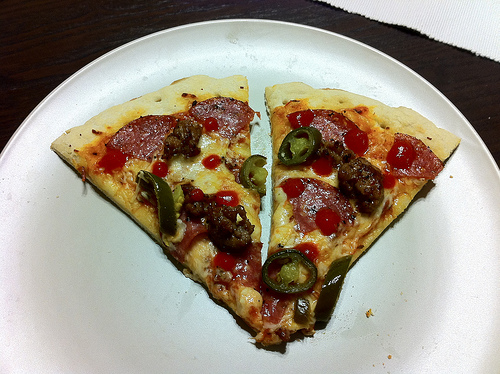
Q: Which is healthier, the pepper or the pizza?
A: The pepper is healthier than the pizza.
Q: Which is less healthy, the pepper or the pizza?
A: The pizza is less healthy than the pepper.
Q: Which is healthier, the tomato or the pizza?
A: The tomato is healthier than the pizza.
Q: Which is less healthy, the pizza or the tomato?
A: The pizza is less healthy than the tomato.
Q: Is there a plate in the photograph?
A: Yes, there is a plate.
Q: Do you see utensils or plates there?
A: Yes, there is a plate.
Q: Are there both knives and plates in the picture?
A: No, there is a plate but no knives.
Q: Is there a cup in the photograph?
A: No, there are no cups.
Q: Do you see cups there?
A: No, there are no cups.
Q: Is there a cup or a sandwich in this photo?
A: No, there are no cups or sandwiches.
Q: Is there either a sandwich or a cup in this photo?
A: No, there are no cups or sandwiches.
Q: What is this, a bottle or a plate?
A: This is a plate.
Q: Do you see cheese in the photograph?
A: Yes, there is cheese.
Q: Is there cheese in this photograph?
A: Yes, there is cheese.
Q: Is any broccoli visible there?
A: No, there is no broccoli.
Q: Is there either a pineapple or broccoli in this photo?
A: No, there are no broccoli or pineapples.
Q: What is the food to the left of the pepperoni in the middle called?
A: The food is cheese.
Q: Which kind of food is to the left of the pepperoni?
A: The food is cheese.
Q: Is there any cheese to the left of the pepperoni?
A: Yes, there is cheese to the left of the pepperoni.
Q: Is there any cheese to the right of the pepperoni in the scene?
A: No, the cheese is to the left of the pepperoni.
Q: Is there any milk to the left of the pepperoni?
A: No, there is cheese to the left of the pepperoni.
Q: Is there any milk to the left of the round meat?
A: No, there is cheese to the left of the pepperoni.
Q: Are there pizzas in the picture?
A: Yes, there is a pizza.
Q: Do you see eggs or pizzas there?
A: Yes, there is a pizza.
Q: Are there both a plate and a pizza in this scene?
A: Yes, there are both a pizza and a plate.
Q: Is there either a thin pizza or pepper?
A: Yes, there is a thin pizza.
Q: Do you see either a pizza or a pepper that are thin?
A: Yes, the pizza is thin.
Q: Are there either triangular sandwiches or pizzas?
A: Yes, there is a triangular pizza.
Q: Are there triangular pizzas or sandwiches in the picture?
A: Yes, there is a triangular pizza.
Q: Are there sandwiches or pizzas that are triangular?
A: Yes, the pizza is triangular.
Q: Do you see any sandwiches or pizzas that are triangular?
A: Yes, the pizza is triangular.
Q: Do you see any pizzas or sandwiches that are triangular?
A: Yes, the pizza is triangular.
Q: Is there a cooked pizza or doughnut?
A: Yes, there is a cooked pizza.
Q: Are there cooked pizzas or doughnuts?
A: Yes, there is a cooked pizza.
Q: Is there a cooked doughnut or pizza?
A: Yes, there is a cooked pizza.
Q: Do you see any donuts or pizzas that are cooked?
A: Yes, the pizza is cooked.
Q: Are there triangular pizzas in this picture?
A: Yes, there is a triangular pizza.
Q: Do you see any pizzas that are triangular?
A: Yes, there is a pizza that is triangular.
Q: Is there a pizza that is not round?
A: Yes, there is a triangular pizza.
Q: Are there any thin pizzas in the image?
A: Yes, there is a thin pizza.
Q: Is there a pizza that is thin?
A: Yes, there is a pizza that is thin.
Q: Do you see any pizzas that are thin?
A: Yes, there is a pizza that is thin.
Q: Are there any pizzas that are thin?
A: Yes, there is a pizza that is thin.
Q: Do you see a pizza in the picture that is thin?
A: Yes, there is a pizza that is thin.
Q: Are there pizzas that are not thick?
A: Yes, there is a thin pizza.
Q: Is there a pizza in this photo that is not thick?
A: Yes, there is a thin pizza.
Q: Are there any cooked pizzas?
A: Yes, there is a cooked pizza.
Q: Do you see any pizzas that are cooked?
A: Yes, there is a pizza that is cooked.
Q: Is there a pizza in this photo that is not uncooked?
A: Yes, there is an cooked pizza.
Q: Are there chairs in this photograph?
A: No, there are no chairs.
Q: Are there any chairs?
A: No, there are no chairs.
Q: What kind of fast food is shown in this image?
A: The fast food is a pizza.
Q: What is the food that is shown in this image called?
A: The food is a pizza.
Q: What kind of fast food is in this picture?
A: The fast food is a pizza.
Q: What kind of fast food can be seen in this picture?
A: The fast food is a pizza.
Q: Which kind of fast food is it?
A: The food is a pizza.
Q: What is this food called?
A: That is a pizza.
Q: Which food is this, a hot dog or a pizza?
A: That is a pizza.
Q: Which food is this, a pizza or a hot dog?
A: That is a pizza.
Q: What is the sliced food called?
A: The food is a pizza.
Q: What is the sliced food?
A: The food is a pizza.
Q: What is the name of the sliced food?
A: The food is a pizza.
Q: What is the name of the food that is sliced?
A: The food is a pizza.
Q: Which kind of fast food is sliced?
A: The fast food is a pizza.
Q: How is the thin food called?
A: The food is a pizza.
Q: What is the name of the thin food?
A: The food is a pizza.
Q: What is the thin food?
A: The food is a pizza.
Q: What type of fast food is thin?
A: The fast food is a pizza.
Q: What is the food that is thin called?
A: The food is a pizza.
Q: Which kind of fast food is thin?
A: The fast food is a pizza.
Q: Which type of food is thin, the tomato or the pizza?
A: The pizza is thin.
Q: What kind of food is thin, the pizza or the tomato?
A: The pizza is thin.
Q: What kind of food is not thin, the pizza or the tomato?
A: The tomato is not thin.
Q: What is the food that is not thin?
A: The food is a tomato.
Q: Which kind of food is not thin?
A: The food is a tomato.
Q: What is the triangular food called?
A: The food is a pizza.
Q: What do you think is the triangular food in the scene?
A: The food is a pizza.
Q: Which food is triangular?
A: The food is a pizza.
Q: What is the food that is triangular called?
A: The food is a pizza.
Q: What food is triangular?
A: The food is a pizza.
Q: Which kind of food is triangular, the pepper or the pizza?
A: The pizza is triangular.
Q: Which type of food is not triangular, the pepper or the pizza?
A: The pepper is not triangular.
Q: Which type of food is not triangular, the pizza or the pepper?
A: The pepper is not triangular.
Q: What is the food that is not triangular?
A: The food is a pepper.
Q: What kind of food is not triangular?
A: The food is a pepper.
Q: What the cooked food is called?
A: The food is a pizza.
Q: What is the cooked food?
A: The food is a pizza.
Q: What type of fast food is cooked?
A: The fast food is a pizza.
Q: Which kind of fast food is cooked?
A: The fast food is a pizza.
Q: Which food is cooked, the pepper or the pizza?
A: The pizza is cooked.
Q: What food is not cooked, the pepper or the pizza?
A: The pepper is not cooked.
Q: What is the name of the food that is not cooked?
A: The food is a pepper.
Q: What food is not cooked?
A: The food is a pepper.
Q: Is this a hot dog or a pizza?
A: This is a pizza.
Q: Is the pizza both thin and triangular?
A: Yes, the pizza is thin and triangular.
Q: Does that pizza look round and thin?
A: No, the pizza is thin but triangular.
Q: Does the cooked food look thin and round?
A: No, the pizza is thin but triangular.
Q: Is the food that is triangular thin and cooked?
A: Yes, the pizza is thin and cooked.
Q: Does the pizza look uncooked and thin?
A: No, the pizza is thin but cooked.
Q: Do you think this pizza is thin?
A: Yes, the pizza is thin.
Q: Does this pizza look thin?
A: Yes, the pizza is thin.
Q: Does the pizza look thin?
A: Yes, the pizza is thin.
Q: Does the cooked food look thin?
A: Yes, the pizza is thin.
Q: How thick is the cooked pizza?
A: The pizza is thin.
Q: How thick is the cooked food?
A: The pizza is thin.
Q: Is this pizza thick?
A: No, the pizza is thin.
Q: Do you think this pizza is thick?
A: No, the pizza is thin.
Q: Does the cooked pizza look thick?
A: No, the pizza is thin.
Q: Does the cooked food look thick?
A: No, the pizza is thin.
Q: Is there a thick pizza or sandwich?
A: No, there is a pizza but it is thin.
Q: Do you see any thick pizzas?
A: No, there is a pizza but it is thin.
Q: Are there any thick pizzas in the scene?
A: No, there is a pizza but it is thin.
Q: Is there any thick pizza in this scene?
A: No, there is a pizza but it is thin.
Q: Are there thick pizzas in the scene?
A: No, there is a pizza but it is thin.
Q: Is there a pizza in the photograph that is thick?
A: No, there is a pizza but it is thin.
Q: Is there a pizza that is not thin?
A: No, there is a pizza but it is thin.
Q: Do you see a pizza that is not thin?
A: No, there is a pizza but it is thin.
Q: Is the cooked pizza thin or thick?
A: The pizza is thin.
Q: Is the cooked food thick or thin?
A: The pizza is thin.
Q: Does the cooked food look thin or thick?
A: The pizza is thin.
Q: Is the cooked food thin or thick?
A: The pizza is thin.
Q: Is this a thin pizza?
A: Yes, this is a thin pizza.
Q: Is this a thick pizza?
A: No, this is a thin pizza.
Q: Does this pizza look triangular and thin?
A: Yes, the pizza is triangular and thin.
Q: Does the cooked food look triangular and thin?
A: Yes, the pizza is triangular and thin.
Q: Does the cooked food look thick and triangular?
A: No, the pizza is triangular but thin.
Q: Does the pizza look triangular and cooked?
A: Yes, the pizza is triangular and cooked.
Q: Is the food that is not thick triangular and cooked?
A: Yes, the pizza is triangular and cooked.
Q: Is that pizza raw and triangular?
A: No, the pizza is triangular but cooked.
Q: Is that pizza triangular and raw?
A: No, the pizza is triangular but cooked.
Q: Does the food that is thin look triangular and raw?
A: No, the pizza is triangular but cooked.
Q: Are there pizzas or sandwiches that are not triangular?
A: No, there is a pizza but it is triangular.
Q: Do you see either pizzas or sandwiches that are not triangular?
A: No, there is a pizza but it is triangular.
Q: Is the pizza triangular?
A: Yes, the pizza is triangular.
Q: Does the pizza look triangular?
A: Yes, the pizza is triangular.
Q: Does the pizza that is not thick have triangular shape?
A: Yes, the pizza is triangular.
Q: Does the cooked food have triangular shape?
A: Yes, the pizza is triangular.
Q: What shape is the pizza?
A: The pizza is triangular.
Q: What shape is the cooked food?
A: The pizza is triangular.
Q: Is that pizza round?
A: No, the pizza is triangular.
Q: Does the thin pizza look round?
A: No, the pizza is triangular.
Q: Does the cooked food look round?
A: No, the pizza is triangular.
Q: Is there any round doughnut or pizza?
A: No, there is a pizza but it is triangular.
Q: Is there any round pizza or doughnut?
A: No, there is a pizza but it is triangular.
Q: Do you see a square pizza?
A: No, there is a pizza but it is triangular.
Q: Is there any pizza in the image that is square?
A: No, there is a pizza but it is triangular.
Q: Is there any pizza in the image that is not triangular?
A: No, there is a pizza but it is triangular.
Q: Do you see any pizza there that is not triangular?
A: No, there is a pizza but it is triangular.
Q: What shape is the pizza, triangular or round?
A: The pizza is triangular.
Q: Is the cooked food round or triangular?
A: The pizza is triangular.